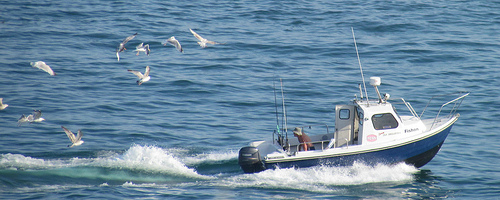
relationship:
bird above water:
[160, 33, 184, 56] [2, 2, 500, 197]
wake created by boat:
[17, 138, 235, 187] [226, 57, 463, 183]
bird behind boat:
[160, 33, 184, 56] [226, 57, 463, 183]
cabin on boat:
[341, 99, 406, 139] [226, 57, 463, 183]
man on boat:
[288, 126, 313, 149] [226, 57, 463, 183]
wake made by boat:
[17, 138, 235, 187] [226, 57, 463, 183]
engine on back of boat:
[236, 141, 266, 174] [226, 57, 463, 183]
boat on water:
[226, 57, 463, 183] [2, 2, 500, 197]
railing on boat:
[283, 138, 347, 157] [226, 57, 463, 183]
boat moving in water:
[226, 57, 463, 183] [2, 2, 500, 197]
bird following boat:
[160, 33, 184, 56] [226, 57, 463, 183]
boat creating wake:
[226, 57, 463, 183] [17, 138, 235, 187]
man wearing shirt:
[288, 126, 313, 149] [295, 135, 316, 146]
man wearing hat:
[288, 126, 313, 149] [293, 126, 304, 135]